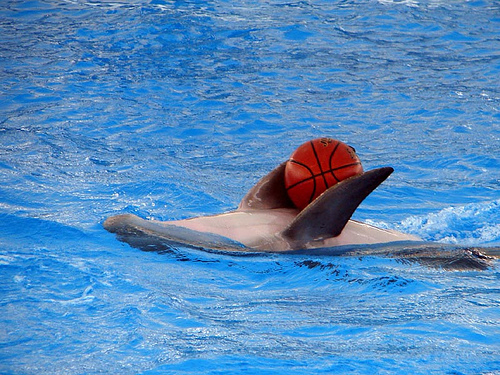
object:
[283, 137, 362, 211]
basketball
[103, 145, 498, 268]
dolphin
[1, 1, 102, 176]
water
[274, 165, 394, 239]
flipper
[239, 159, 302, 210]
flipper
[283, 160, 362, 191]
stripe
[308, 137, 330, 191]
stripe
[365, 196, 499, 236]
wave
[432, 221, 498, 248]
wave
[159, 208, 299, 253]
chest